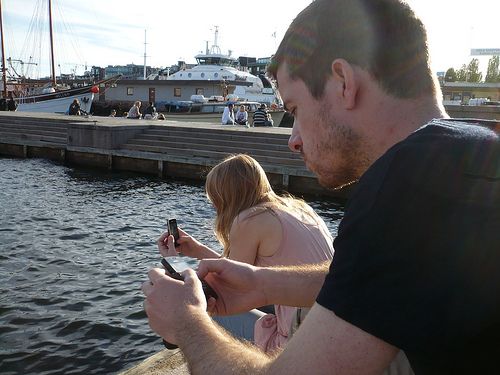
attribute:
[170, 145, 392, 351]
lady — young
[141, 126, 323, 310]
woman — blonde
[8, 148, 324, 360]
water — choppy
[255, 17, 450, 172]
man — brown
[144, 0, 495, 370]
man — looking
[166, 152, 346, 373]
lady — young, focused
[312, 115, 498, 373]
sweater — white and black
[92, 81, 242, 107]
building — one story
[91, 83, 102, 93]
ball — red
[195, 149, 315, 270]
lady — young, texting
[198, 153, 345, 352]
lady — young, pretty, pink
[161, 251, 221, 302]
cell phone — black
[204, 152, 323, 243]
hair — long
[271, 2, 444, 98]
hair — short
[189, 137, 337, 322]
woman — looking at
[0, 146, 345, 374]
water — calm